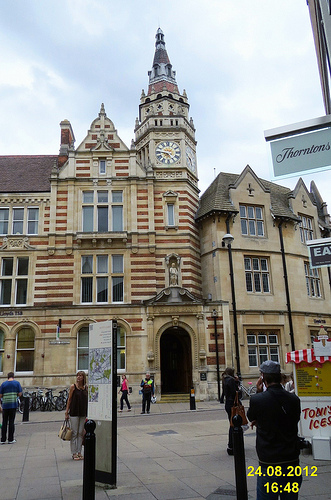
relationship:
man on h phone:
[247, 351, 310, 499] [257, 371, 265, 386]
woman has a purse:
[65, 372, 87, 460] [57, 409, 76, 442]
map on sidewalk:
[89, 322, 113, 423] [2, 421, 326, 500]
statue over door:
[166, 257, 182, 284] [159, 327, 191, 397]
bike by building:
[38, 384, 53, 411] [0, 27, 225, 400]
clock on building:
[152, 137, 177, 165] [0, 27, 225, 400]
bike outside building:
[38, 384, 53, 411] [0, 27, 225, 400]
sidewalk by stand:
[2, 421, 326, 500] [288, 328, 330, 459]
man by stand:
[247, 351, 310, 499] [288, 328, 330, 459]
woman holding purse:
[65, 372, 87, 460] [57, 409, 76, 442]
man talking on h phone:
[247, 351, 310, 499] [257, 371, 265, 386]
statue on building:
[166, 257, 182, 284] [0, 27, 225, 400]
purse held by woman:
[57, 409, 76, 442] [65, 372, 87, 460]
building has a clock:
[0, 27, 225, 400] [152, 137, 177, 165]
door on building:
[159, 327, 191, 397] [0, 27, 225, 400]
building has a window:
[0, 27, 225, 400] [95, 204, 110, 232]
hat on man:
[258, 357, 285, 374] [247, 351, 310, 499]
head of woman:
[74, 371, 87, 388] [65, 372, 87, 460]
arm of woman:
[64, 386, 75, 415] [65, 372, 87, 460]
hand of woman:
[62, 410, 72, 423] [65, 372, 87, 460]